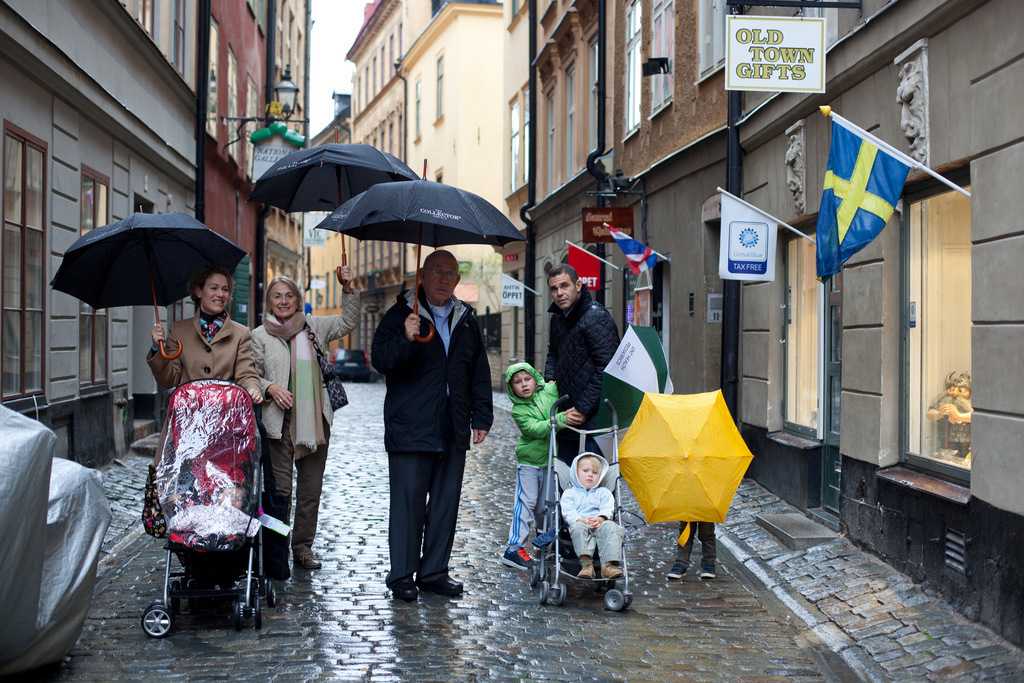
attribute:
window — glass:
[639, 1, 691, 133]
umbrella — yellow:
[605, 376, 772, 532]